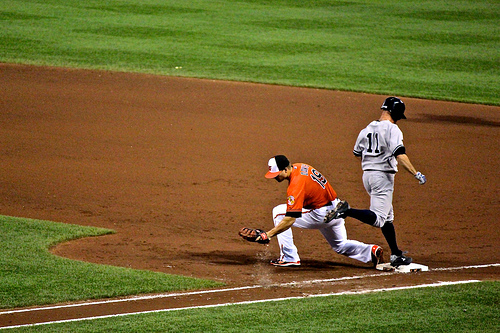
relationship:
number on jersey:
[364, 133, 385, 154] [352, 119, 407, 174]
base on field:
[374, 255, 431, 274] [59, 79, 464, 291]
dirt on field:
[127, 104, 208, 144] [59, 79, 464, 291]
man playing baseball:
[239, 155, 395, 275] [30, 27, 479, 275]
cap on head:
[269, 159, 285, 172] [256, 153, 298, 184]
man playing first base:
[254, 139, 343, 259] [374, 255, 431, 274]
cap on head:
[264, 154, 290, 179] [256, 153, 298, 184]